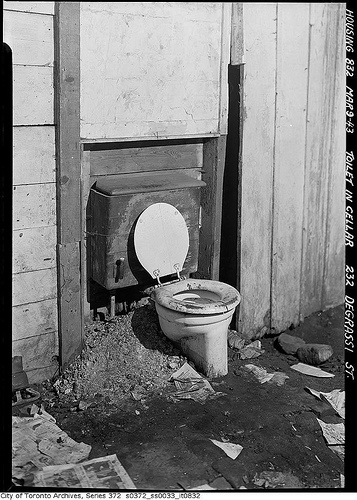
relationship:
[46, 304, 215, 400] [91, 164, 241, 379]
dirt surrounds toilet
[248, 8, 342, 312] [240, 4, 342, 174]
wall contains wood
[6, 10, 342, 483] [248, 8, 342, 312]
picture of wall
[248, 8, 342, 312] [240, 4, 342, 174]
wall made of wood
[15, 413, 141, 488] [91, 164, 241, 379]
newspaper used for toilet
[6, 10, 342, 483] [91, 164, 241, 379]
picture of toilet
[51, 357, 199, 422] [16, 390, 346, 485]
rocks are on ground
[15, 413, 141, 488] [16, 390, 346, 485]
newspaper on ground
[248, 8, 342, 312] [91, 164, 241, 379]
wall next to toilet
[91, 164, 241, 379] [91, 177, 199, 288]
toilet has tank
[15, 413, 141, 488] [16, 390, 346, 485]
newspaper on floor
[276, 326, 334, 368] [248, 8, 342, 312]
stone near wall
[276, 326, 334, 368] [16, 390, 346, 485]
stone on floor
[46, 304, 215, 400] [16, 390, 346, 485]
dirt on floor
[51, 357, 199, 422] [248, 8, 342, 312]
rocks near wall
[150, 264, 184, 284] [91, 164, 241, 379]
hinge on toilet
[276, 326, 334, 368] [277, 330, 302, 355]
stone near another stone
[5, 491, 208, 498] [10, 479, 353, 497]
writing on bottom